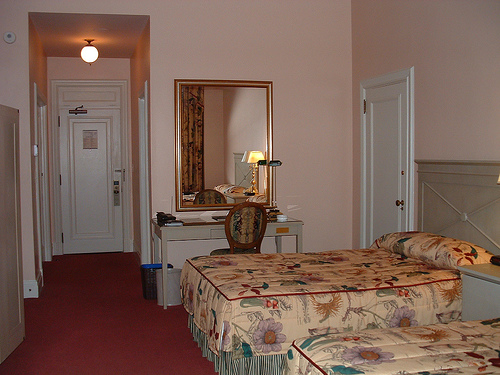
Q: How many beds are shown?
A: 2.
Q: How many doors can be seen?
A: 2.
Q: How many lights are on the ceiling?
A: 1.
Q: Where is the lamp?
A: Between the beds.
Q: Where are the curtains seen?
A: Mirror.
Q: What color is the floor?
A: Red.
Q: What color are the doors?
A: White.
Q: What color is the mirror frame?
A: Gold.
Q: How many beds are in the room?
A: Two.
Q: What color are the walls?
A: Pink.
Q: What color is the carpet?
A: Rose colored.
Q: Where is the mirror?
A: On the wall above a table.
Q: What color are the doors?
A: White.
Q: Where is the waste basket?
A: Under the small table.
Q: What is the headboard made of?
A: Wood.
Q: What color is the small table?
A: White.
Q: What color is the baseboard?
A: White.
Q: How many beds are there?
A: 2.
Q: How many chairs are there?
A: 1.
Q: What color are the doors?
A: White.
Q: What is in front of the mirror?
A: A table.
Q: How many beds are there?
A: Two.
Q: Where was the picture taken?
A: Hotel room.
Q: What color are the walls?
A: Pink.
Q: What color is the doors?
A: White.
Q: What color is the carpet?
A: Red.